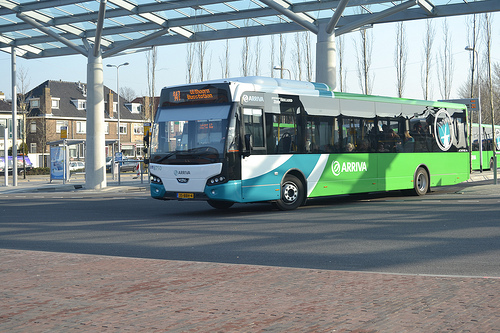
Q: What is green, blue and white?
A: A bus.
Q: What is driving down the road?
A: Bus.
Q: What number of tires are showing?
A: 3.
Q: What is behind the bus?
A: Homes.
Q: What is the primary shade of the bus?
A: Green.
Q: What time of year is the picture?
A: Winter.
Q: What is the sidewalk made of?
A: Bricks.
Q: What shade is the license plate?
A: Yellow.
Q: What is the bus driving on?
A: Asphalt.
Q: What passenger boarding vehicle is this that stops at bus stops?
A: Bus.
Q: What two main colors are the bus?
A: Green and blue.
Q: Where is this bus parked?
A: Terminal.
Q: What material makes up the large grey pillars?
A: Concrete.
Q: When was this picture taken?
A: The daytime.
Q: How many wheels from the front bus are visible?
A: Three.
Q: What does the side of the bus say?
A: Arriva.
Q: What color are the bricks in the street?
A: Red.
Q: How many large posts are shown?
A: 2.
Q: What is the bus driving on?
A: The street.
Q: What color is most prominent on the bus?
A: Green.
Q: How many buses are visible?
A: 2.